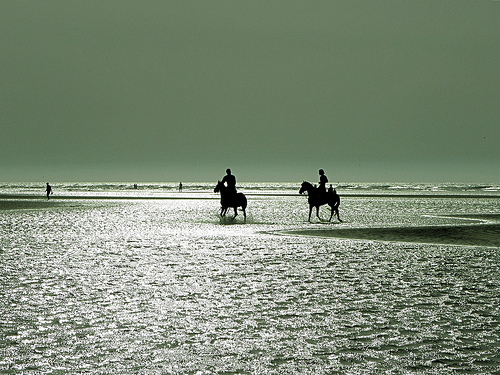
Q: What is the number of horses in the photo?
A: Two.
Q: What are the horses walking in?
A: Water.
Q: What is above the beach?
A: Sky.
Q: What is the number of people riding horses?
A: Two.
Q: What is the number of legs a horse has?
A: Four.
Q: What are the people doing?
A: Riding horses.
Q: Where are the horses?
A: Beach.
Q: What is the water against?
A: Sand.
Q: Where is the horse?
A: On the beach.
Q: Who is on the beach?
A: Horses and people.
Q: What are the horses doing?
A: Walking.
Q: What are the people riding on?
A: Horses.